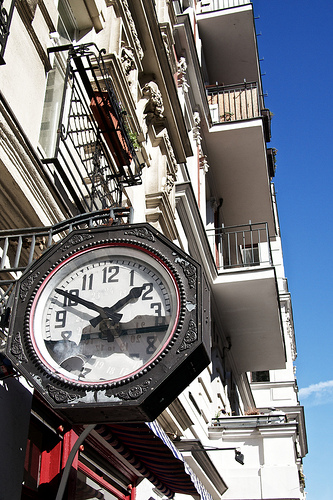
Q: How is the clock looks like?
A: White and black.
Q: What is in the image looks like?
A: Clock.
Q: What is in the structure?
A: Tall building.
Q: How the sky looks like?
A: Clouds.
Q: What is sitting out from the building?
A: Clock.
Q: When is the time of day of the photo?
A: Daytime.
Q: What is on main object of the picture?
A: Clock.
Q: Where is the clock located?
A: On a building.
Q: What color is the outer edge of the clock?
A: Black.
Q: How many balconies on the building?
A: Three.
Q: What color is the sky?
A: Blue.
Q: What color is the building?
A: White.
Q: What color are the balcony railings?
A: Black.